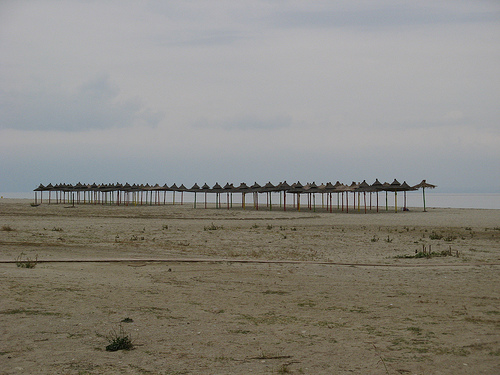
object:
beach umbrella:
[413, 172, 438, 213]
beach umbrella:
[399, 178, 414, 212]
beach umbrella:
[387, 178, 400, 213]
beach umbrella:
[337, 178, 354, 212]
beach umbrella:
[321, 180, 340, 213]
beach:
[0, 191, 499, 219]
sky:
[0, 17, 480, 177]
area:
[218, 275, 446, 356]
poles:
[24, 190, 435, 218]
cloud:
[109, 95, 474, 143]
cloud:
[0, 64, 331, 134]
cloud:
[13, 9, 496, 47]